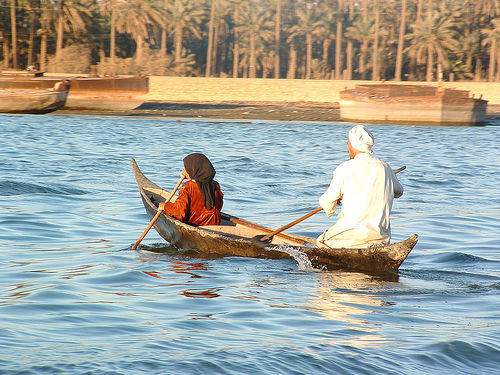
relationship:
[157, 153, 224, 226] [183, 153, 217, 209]
woman wearing scarf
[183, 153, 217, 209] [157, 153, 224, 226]
scarf on woman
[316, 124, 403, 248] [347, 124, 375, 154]
man wearing turban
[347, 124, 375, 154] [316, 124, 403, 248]
turban on man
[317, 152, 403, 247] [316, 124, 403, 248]
robe on man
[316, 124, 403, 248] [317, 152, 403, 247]
man wearing robe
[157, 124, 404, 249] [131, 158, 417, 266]
couple in boat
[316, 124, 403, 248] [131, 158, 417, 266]
man in boat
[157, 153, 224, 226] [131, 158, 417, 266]
woman in boat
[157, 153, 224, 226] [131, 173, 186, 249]
woman holding oar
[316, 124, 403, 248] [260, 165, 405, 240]
man holding oar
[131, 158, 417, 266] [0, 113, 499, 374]
boat in water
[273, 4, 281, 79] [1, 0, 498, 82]
palm tree in group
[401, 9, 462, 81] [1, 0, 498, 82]
palm tree in group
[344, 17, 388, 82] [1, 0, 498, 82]
palm tree in group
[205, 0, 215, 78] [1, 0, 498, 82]
palm tree in group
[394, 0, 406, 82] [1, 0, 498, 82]
palm tree in group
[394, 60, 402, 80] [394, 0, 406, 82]
trunk of palm tree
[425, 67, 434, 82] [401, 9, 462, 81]
trunk of palm tree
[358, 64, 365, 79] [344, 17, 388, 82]
trunk of palm tree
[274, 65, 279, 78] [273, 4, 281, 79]
trunk of palm tree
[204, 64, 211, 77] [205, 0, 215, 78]
trunk of palm tree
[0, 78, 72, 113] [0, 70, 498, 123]
boat on shore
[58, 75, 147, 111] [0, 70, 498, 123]
boat on shore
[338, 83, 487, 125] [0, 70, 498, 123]
boat on shore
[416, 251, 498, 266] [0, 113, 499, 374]
wave in water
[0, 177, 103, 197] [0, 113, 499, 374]
wave in water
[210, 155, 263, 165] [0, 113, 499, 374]
wave in water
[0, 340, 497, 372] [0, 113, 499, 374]
wave in water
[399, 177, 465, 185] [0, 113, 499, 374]
wave in water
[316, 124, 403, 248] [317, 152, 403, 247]
man in robe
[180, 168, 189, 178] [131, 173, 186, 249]
hand holding oar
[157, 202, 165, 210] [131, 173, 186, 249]
hand holding oar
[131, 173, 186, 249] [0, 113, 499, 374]
oar in water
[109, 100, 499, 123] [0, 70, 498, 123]
dirt on shore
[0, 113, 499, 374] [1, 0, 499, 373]
water in image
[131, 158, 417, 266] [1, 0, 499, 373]
boat in image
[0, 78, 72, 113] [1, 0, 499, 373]
boat in image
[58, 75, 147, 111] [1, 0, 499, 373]
boat in image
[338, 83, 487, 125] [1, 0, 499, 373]
boat in image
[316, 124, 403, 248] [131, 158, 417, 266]
man on boat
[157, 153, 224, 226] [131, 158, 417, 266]
woman on boat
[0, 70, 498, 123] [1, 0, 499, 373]
land in image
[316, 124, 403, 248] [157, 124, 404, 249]
man in couple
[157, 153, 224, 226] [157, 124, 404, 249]
woman in couple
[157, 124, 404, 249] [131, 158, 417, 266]
couple on boat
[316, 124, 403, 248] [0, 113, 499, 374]
man on water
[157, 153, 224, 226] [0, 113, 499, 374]
woman on water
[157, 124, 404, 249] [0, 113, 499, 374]
couple on water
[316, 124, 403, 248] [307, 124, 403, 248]
man in white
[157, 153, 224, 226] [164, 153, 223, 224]
woman in arabic dressing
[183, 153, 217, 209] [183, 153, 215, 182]
scarf on head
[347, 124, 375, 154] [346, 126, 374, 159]
turban on head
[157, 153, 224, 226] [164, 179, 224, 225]
woman wearing shirt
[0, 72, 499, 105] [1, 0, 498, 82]
sand in front of group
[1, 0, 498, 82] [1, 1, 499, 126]
group in background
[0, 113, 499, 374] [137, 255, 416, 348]
water rippling reflection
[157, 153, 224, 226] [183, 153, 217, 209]
woman with scarf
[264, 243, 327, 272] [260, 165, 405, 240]
splash around oar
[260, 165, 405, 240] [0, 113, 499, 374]
oar splashing water